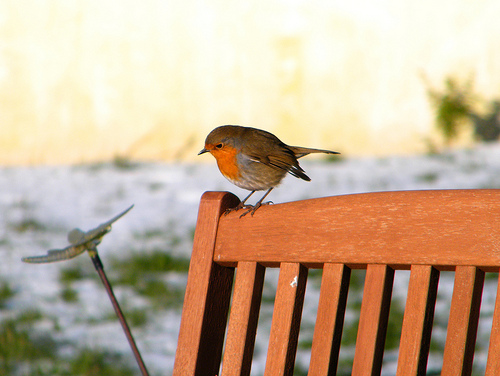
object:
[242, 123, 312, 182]
birds wing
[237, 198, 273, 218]
foot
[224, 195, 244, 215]
foot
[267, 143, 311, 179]
feathers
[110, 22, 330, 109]
day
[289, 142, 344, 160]
tail feather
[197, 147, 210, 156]
beak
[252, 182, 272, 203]
leg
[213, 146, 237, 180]
chest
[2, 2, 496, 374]
picture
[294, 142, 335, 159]
tail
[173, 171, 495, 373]
bench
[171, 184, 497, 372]
wood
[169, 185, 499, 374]
wooden bench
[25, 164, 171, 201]
snow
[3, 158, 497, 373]
ground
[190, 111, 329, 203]
bird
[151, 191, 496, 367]
chair back